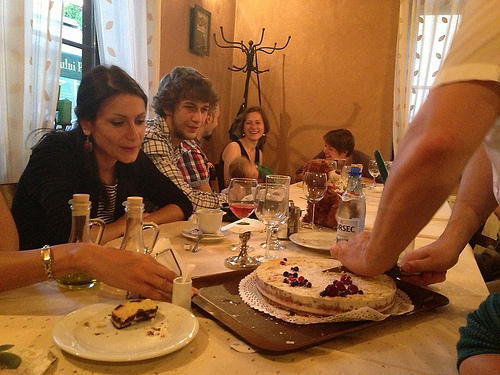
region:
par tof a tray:
[238, 323, 255, 341]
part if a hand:
[336, 215, 383, 315]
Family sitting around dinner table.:
[40, 30, 497, 368]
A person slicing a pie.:
[240, 218, 412, 336]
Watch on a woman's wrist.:
[33, 238, 60, 280]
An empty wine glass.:
[247, 178, 299, 253]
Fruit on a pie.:
[282, 262, 319, 301]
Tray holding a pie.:
[157, 236, 452, 351]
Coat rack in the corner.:
[213, 23, 298, 116]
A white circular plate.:
[55, 290, 199, 365]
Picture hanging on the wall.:
[185, 3, 216, 55]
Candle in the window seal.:
[50, 83, 76, 132]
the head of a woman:
[71, 62, 151, 171]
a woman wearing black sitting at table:
[11, 61, 191, 237]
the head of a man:
[152, 65, 222, 147]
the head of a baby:
[227, 154, 262, 178]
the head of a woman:
[232, 104, 271, 141]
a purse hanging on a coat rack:
[212, 22, 298, 134]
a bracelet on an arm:
[39, 242, 57, 288]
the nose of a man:
[189, 106, 207, 128]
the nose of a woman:
[121, 116, 142, 146]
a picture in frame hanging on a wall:
[187, 5, 214, 58]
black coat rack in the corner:
[208, 23, 293, 108]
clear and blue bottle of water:
[333, 161, 367, 241]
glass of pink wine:
[227, 173, 258, 253]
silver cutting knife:
[321, 260, 450, 277]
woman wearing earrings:
[238, 130, 267, 137]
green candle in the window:
[56, 93, 76, 126]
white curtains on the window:
[0, 0, 162, 187]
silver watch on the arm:
[36, 243, 56, 285]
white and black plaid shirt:
[139, 113, 229, 213]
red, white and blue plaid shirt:
[174, 138, 211, 183]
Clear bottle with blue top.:
[331, 166, 368, 250]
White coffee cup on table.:
[188, 203, 225, 232]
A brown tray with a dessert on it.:
[192, 240, 453, 359]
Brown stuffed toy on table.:
[300, 151, 351, 228]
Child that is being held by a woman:
[221, 150, 275, 185]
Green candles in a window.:
[52, 84, 74, 131]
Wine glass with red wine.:
[229, 170, 257, 220]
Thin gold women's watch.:
[38, 241, 55, 277]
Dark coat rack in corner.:
[213, 14, 297, 139]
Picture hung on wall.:
[186, 0, 217, 58]